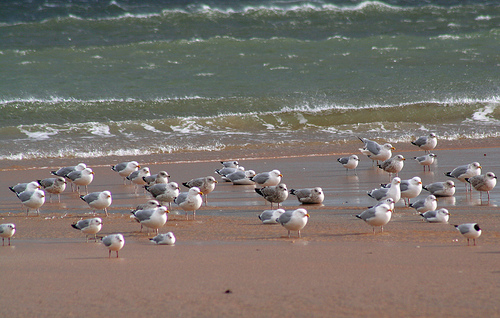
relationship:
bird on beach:
[347, 187, 409, 237] [1, 131, 498, 314]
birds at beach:
[276, 207, 308, 235] [1, 147, 500, 314]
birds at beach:
[452, 222, 481, 241] [1, 147, 500, 314]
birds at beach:
[358, 204, 391, 231] [1, 147, 500, 314]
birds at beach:
[174, 186, 204, 216] [1, 147, 500, 314]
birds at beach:
[132, 205, 168, 230] [1, 147, 500, 314]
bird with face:
[451, 219, 482, 248] [472, 220, 483, 232]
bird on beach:
[79, 190, 112, 217] [1, 131, 498, 314]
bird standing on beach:
[79, 190, 112, 217] [1, 147, 500, 314]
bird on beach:
[98, 232, 126, 258] [82, 62, 497, 285]